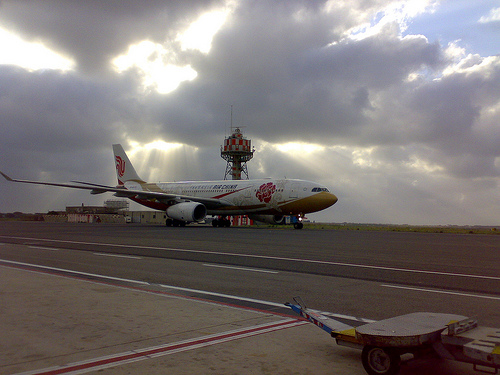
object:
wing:
[1, 171, 226, 207]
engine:
[167, 199, 207, 225]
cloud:
[0, 0, 227, 65]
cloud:
[0, 61, 163, 146]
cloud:
[136, 146, 499, 225]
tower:
[219, 125, 254, 180]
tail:
[111, 141, 143, 183]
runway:
[0, 217, 497, 373]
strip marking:
[2, 234, 499, 280]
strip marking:
[26, 243, 60, 251]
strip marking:
[92, 250, 142, 259]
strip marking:
[201, 261, 278, 273]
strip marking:
[379, 280, 496, 300]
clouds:
[140, 26, 500, 181]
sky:
[0, 0, 499, 227]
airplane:
[7, 142, 338, 232]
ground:
[0, 224, 499, 374]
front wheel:
[293, 222, 305, 229]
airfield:
[0, 196, 498, 373]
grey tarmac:
[0, 218, 499, 338]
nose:
[322, 188, 338, 208]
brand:
[255, 181, 277, 204]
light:
[121, 128, 376, 187]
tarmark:
[0, 213, 499, 375]